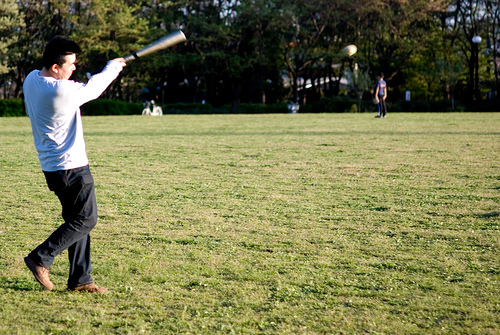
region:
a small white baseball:
[342, 41, 363, 57]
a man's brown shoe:
[22, 254, 54, 291]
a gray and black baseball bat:
[115, 29, 186, 59]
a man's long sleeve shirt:
[26, 58, 121, 182]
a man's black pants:
[27, 167, 104, 285]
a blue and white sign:
[404, 88, 411, 101]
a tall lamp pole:
[469, 33, 488, 110]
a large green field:
[0, 111, 499, 333]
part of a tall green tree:
[221, 0, 295, 108]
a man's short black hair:
[38, 38, 75, 75]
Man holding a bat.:
[18, 20, 235, 322]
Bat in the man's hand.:
[23, 30, 192, 85]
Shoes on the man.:
[25, 234, 176, 318]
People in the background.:
[310, 56, 452, 126]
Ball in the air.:
[339, 39, 370, 53]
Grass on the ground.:
[218, 81, 383, 250]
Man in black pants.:
[27, 22, 177, 292]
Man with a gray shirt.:
[17, 33, 222, 280]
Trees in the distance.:
[254, 7, 471, 167]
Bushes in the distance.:
[157, 74, 392, 186]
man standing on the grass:
[16, 21, 153, 321]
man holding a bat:
[14, 16, 196, 306]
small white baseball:
[339, 38, 361, 63]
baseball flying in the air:
[343, 39, 365, 61]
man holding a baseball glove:
[372, 71, 397, 116]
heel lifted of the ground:
[21, 256, 61, 296]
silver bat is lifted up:
[84, 24, 189, 92]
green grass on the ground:
[4, 107, 496, 334]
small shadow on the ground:
[476, 203, 499, 223]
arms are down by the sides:
[369, 81, 395, 107]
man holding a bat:
[35, 23, 219, 138]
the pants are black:
[14, 153, 124, 287]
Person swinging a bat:
[17, 24, 227, 312]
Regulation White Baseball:
[312, 33, 367, 71]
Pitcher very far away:
[363, 75, 400, 137]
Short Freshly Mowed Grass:
[116, 116, 498, 325]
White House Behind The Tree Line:
[241, 56, 361, 117]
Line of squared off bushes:
[2, 85, 487, 115]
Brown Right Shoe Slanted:
[17, 246, 57, 298]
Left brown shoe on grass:
[70, 278, 109, 301]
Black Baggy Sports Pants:
[11, 152, 128, 291]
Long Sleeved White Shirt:
[12, 60, 139, 174]